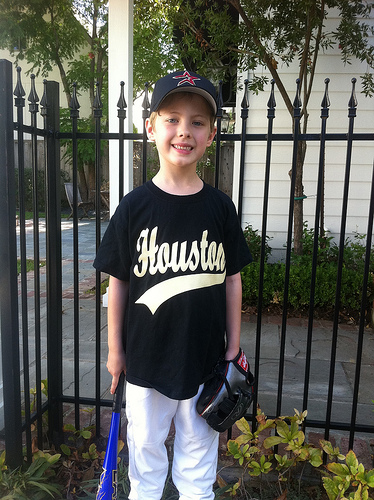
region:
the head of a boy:
[139, 63, 221, 173]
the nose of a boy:
[173, 117, 192, 139]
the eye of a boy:
[163, 111, 180, 123]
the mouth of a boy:
[165, 137, 194, 152]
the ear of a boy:
[201, 122, 219, 145]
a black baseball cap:
[145, 63, 223, 118]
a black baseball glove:
[191, 344, 263, 433]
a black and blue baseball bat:
[85, 362, 128, 495]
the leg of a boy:
[117, 381, 174, 496]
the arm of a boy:
[88, 203, 132, 358]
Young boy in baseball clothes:
[66, 63, 313, 496]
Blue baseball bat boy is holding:
[84, 352, 150, 497]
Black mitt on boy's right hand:
[189, 324, 275, 477]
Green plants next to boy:
[201, 380, 371, 494]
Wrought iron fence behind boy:
[0, 43, 373, 498]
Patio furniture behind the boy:
[40, 160, 132, 249]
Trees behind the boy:
[1, 6, 368, 286]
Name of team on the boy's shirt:
[109, 214, 261, 308]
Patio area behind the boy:
[12, 216, 372, 422]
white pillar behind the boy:
[99, 1, 143, 205]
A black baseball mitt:
[195, 349, 256, 434]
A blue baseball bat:
[92, 374, 126, 497]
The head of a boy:
[144, 66, 217, 182]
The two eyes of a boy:
[164, 116, 208, 128]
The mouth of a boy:
[169, 141, 197, 156]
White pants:
[122, 399, 220, 498]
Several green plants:
[221, 405, 370, 495]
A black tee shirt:
[92, 174, 252, 402]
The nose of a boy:
[175, 118, 192, 139]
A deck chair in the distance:
[61, 180, 94, 218]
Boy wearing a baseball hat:
[128, 59, 236, 125]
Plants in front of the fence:
[272, 414, 339, 492]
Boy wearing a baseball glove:
[196, 338, 267, 430]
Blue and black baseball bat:
[87, 349, 114, 495]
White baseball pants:
[119, 364, 229, 497]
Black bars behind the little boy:
[8, 215, 84, 360]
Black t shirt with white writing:
[106, 169, 265, 406]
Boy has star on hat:
[154, 66, 236, 99]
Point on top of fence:
[113, 78, 132, 128]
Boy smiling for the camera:
[159, 112, 212, 162]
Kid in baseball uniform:
[66, 48, 287, 465]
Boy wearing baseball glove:
[192, 333, 256, 427]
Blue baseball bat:
[89, 330, 138, 495]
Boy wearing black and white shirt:
[105, 176, 279, 405]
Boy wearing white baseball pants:
[99, 179, 244, 490]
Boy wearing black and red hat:
[112, 55, 238, 182]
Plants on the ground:
[222, 389, 350, 488]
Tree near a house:
[201, 21, 347, 271]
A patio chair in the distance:
[56, 186, 97, 222]